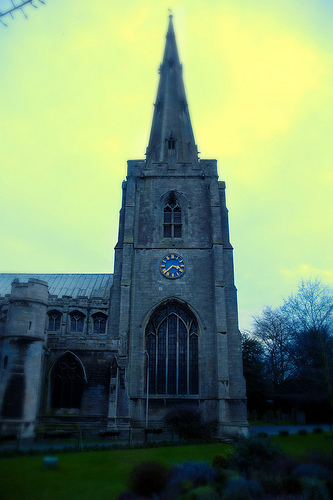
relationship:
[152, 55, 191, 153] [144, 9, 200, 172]
windows dot spire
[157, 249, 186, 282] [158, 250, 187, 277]
clock has roman numerals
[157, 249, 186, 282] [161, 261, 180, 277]
clock has hands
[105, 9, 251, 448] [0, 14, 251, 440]
tower on side of building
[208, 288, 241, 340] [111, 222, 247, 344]
block on tower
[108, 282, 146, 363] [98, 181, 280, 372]
block on tower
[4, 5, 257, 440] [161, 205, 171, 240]
building has window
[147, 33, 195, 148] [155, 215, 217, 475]
spire on top of building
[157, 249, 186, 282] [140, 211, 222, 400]
clock on outside of tower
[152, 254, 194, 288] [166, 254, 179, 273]
clock with numbers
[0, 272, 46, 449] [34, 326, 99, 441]
tower on outside of building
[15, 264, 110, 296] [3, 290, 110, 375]
roof on top of building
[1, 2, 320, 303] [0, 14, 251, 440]
glow surrounds building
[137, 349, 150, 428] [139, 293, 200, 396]
drain pipe in front of glass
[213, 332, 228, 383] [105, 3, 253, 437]
block on tower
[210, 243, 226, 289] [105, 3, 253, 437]
block on tower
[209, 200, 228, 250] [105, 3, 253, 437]
block on tower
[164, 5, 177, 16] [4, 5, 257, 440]
statue on top of building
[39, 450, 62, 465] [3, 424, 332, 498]
item on ground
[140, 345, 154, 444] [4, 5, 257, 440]
light post in front of building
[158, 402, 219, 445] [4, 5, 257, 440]
bush next to building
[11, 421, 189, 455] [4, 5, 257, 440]
gate surrounding building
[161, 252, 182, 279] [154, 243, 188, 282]
numbers on clock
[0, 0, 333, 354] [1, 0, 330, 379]
clouds in sky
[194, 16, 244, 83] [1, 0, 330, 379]
clouds in sky